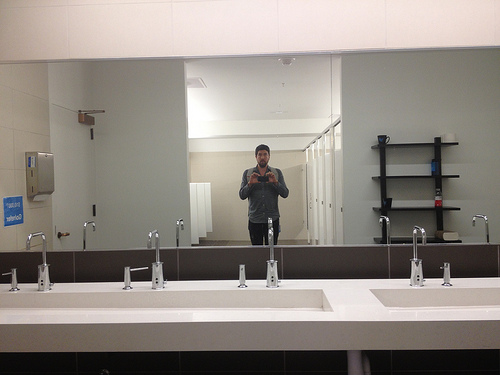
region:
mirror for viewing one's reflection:
[2, 58, 494, 250]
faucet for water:
[143, 227, 166, 287]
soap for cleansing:
[121, 263, 148, 289]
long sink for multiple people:
[1, 288, 328, 313]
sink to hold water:
[0, 289, 329, 314]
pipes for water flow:
[338, 350, 370, 373]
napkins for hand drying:
[24, 153, 56, 204]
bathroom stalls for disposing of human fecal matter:
[301, 138, 345, 243]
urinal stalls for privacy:
[188, 178, 220, 244]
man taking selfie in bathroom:
[239, 138, 289, 243]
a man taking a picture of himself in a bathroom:
[148, 109, 393, 246]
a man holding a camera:
[235, 142, 292, 246]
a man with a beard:
[246, 140, 275, 169]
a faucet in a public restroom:
[121, 225, 170, 286]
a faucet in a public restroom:
[19, 214, 57, 293]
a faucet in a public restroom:
[258, 210, 292, 289]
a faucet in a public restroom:
[401, 219, 431, 286]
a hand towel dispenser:
[21, 141, 60, 202]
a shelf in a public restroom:
[372, 125, 467, 242]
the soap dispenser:
[114, 260, 149, 290]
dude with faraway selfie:
[233, 134, 295, 246]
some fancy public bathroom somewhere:
[0, 0, 499, 374]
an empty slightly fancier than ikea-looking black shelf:
[368, 123, 465, 244]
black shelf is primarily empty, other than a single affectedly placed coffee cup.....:
[366, 127, 400, 153]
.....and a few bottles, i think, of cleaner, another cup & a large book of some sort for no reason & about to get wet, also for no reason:
[363, 116, 471, 241]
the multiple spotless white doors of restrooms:
[187, 116, 343, 246]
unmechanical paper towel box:
[19, 143, 57, 209]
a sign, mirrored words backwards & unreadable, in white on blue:
[0, 190, 31, 231]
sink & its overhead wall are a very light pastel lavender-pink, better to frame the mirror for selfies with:
[0, 1, 499, 352]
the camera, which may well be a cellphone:
[249, 169, 274, 188]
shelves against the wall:
[369, 123, 473, 244]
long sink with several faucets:
[3, 233, 330, 320]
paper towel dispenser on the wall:
[22, 138, 63, 212]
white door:
[51, 99, 103, 250]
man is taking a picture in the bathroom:
[235, 133, 298, 233]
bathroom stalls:
[301, 146, 338, 241]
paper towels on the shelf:
[436, 225, 463, 245]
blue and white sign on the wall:
[3, 191, 26, 233]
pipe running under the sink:
[338, 351, 380, 373]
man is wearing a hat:
[252, 140, 270, 152]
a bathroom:
[3, 5, 482, 373]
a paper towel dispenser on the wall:
[26, 150, 60, 202]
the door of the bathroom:
[45, 110, 112, 249]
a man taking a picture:
[247, 142, 287, 242]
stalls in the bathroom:
[298, 135, 351, 242]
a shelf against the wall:
[377, 130, 452, 238]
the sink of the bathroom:
[11, 285, 331, 321]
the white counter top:
[328, 273, 373, 319]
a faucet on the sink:
[405, 223, 431, 280]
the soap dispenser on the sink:
[436, 258, 451, 282]